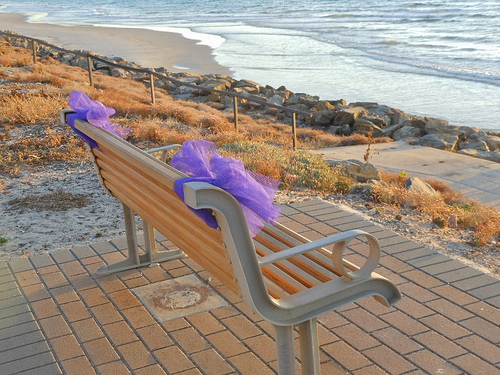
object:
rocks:
[466, 140, 489, 152]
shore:
[0, 11, 234, 80]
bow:
[165, 138, 283, 249]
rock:
[391, 125, 421, 142]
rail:
[0, 32, 315, 152]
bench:
[58, 107, 403, 375]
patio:
[0, 198, 500, 375]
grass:
[0, 31, 500, 248]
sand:
[0, 30, 500, 275]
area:
[0, 29, 499, 275]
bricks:
[446, 353, 500, 375]